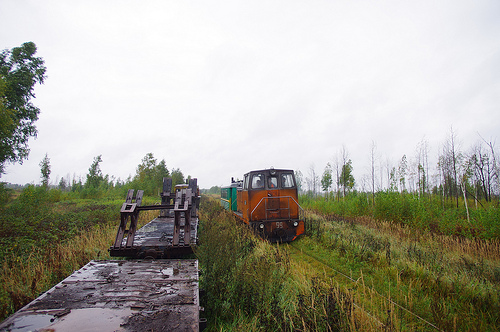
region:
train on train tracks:
[215, 166, 314, 244]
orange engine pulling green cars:
[208, 163, 314, 245]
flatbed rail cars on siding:
[22, 163, 211, 325]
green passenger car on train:
[211, 172, 243, 214]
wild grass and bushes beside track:
[296, 156, 496, 302]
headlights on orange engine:
[257, 217, 302, 238]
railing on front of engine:
[243, 186, 305, 234]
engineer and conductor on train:
[248, 169, 292, 188]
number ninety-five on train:
[268, 216, 293, 233]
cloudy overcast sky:
[47, 84, 480, 186]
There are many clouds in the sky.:
[35, 6, 486, 153]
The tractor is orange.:
[227, 146, 312, 263]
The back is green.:
[187, 145, 282, 240]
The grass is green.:
[335, 210, 495, 325]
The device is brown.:
[41, 162, 162, 322]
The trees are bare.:
[341, 137, 496, 192]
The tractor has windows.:
[230, 157, 311, 193]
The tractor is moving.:
[260, 240, 446, 325]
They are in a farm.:
[25, 10, 495, 315]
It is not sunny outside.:
[31, 36, 496, 324]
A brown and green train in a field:
[198, 144, 325, 251]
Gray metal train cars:
[1, 166, 209, 328]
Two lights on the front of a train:
[254, 219, 302, 233]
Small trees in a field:
[317, 130, 483, 196]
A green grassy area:
[355, 210, 470, 275]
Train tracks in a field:
[290, 240, 425, 325]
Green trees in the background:
[80, 140, 165, 180]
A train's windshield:
[245, 170, 295, 190]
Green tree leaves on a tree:
[0, 35, 45, 145]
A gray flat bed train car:
[0, 251, 200, 326]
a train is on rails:
[205, 154, 322, 258]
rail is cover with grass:
[280, 243, 434, 330]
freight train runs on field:
[210, 159, 312, 253]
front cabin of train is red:
[236, 160, 313, 250]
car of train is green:
[211, 176, 251, 214]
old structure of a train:
[7, 161, 218, 326]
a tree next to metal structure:
[1, 30, 53, 195]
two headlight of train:
[253, 216, 299, 231]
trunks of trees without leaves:
[302, 122, 497, 222]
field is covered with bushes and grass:
[14, 153, 499, 330]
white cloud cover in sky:
[318, 44, 407, 103]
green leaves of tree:
[5, 58, 35, 126]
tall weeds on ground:
[222, 254, 324, 325]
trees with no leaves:
[466, 151, 497, 181]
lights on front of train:
[249, 215, 304, 234]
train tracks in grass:
[342, 280, 384, 312]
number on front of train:
[268, 216, 290, 238]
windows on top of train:
[244, 170, 299, 197]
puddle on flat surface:
[154, 260, 183, 290]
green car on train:
[213, 177, 243, 214]